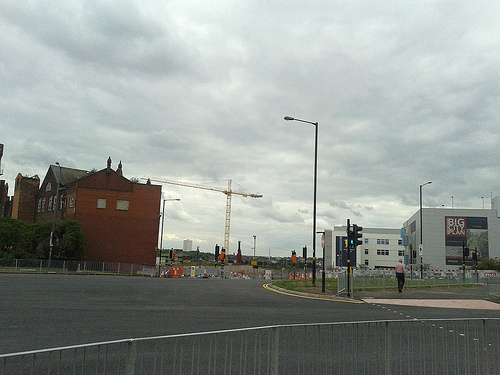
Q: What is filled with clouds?
A: A sky.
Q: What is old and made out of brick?
A: A building.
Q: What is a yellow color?
A: A construction crane.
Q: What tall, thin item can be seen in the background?
A: A crane.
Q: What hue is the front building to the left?
A: Red brick.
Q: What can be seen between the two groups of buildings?
A: A construction site.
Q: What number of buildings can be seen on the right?
A: Two.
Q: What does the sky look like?
A: Gray and cloudy.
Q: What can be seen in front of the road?
A: A silver metal fence.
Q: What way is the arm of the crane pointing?
A: Left.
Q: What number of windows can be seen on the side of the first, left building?
A: Two.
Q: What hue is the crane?
A: It is orange.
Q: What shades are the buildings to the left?
A: Red and brown.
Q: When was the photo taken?
A: Daytime.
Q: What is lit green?
A: Traffic light.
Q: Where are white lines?
A: On the road.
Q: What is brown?
A: A building.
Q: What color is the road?
A: Dark gray.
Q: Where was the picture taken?
A: On the street.